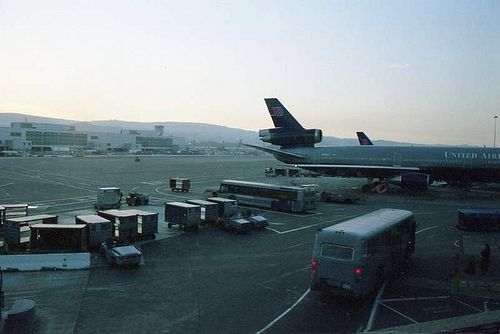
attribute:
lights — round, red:
[308, 257, 368, 284]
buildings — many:
[1, 108, 223, 151]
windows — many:
[218, 182, 298, 200]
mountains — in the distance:
[1, 112, 421, 159]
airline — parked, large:
[240, 92, 499, 198]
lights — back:
[354, 266, 361, 275]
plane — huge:
[240, 91, 498, 193]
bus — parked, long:
[215, 173, 333, 218]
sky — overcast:
[0, 0, 497, 145]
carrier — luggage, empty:
[164, 178, 192, 195]